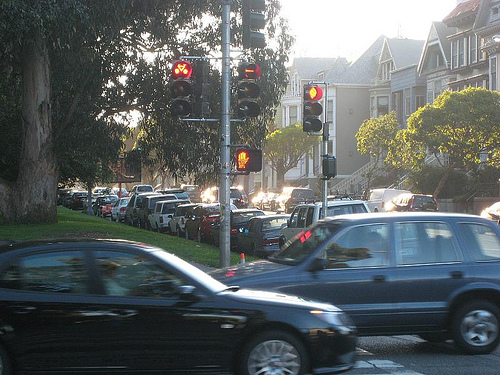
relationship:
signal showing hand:
[229, 144, 327, 209] [232, 141, 253, 176]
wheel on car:
[251, 327, 293, 364] [2, 223, 360, 374]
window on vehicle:
[320, 223, 392, 269] [207, 211, 499, 348]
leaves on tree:
[354, 84, 483, 178] [404, 86, 498, 195]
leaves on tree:
[354, 84, 483, 178] [387, 127, 427, 174]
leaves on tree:
[354, 84, 483, 178] [356, 111, 396, 153]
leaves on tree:
[354, 84, 483, 178] [267, 125, 324, 189]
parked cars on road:
[58, 180, 375, 253] [369, 343, 458, 371]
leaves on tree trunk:
[92, 28, 159, 98] [14, 44, 68, 224]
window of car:
[320, 223, 392, 269] [208, 215, 498, 355]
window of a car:
[320, 223, 392, 269] [242, 166, 497, 331]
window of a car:
[319, 204, 367, 221] [276, 195, 373, 246]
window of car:
[285, 202, 314, 227] [276, 195, 373, 246]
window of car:
[101, 238, 185, 305] [2, 223, 360, 374]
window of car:
[243, 216, 262, 235] [236, 215, 279, 256]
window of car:
[101, 238, 185, 305] [171, 136, 497, 370]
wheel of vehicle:
[461, 306, 498, 350] [304, 222, 484, 284]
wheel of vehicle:
[251, 327, 293, 364] [26, 247, 333, 336]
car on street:
[242, 201, 492, 309] [239, 164, 337, 234]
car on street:
[2, 223, 360, 374] [239, 164, 337, 234]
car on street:
[282, 192, 394, 255] [239, 164, 337, 234]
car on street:
[239, 209, 289, 252] [239, 164, 337, 234]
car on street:
[218, 203, 265, 245] [239, 164, 337, 234]